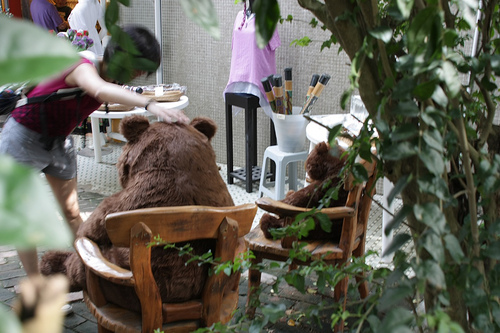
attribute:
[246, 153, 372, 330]
chair — wooden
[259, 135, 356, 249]
bear — small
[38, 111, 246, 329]
bear — large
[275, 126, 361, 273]
bear — small